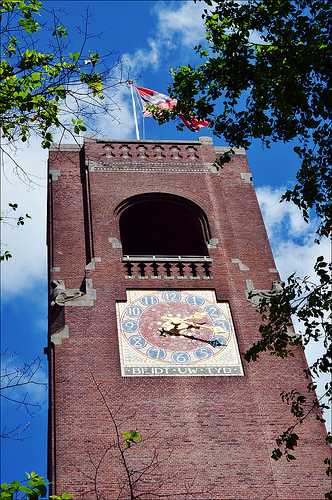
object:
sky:
[122, 12, 185, 83]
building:
[89, 149, 221, 277]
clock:
[115, 280, 242, 396]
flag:
[126, 76, 207, 149]